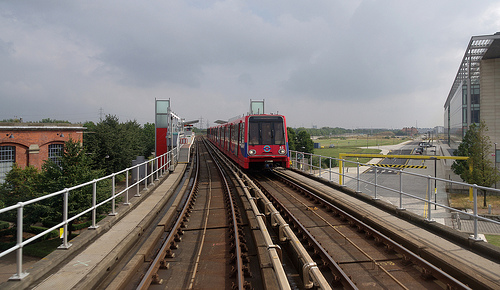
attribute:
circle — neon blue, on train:
[262, 140, 275, 152]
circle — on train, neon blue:
[264, 144, 271, 154]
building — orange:
[7, 113, 116, 196]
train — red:
[192, 104, 313, 189]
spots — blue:
[254, 133, 286, 171]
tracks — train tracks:
[195, 135, 438, 288]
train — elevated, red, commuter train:
[198, 110, 300, 178]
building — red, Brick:
[0, 118, 95, 209]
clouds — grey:
[90, 15, 409, 107]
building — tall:
[436, 40, 481, 203]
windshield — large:
[249, 119, 285, 145]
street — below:
[381, 136, 438, 200]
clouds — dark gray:
[0, 4, 437, 109]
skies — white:
[2, 2, 498, 130]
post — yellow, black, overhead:
[361, 162, 427, 168]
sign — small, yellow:
[59, 228, 64, 238]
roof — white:
[0, 123, 89, 132]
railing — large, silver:
[0, 146, 180, 283]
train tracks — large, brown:
[91, 129, 475, 289]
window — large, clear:
[247, 117, 284, 144]